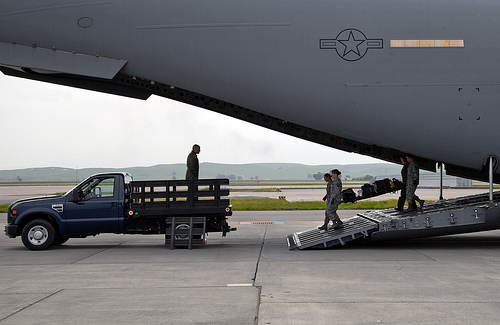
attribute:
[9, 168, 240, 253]
truck — black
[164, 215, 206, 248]
item — wooden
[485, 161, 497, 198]
pole — silver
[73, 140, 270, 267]
truck — blue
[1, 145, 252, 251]
truck — blue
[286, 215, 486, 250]
airplane ramp — silver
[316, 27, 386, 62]
emblem — black 